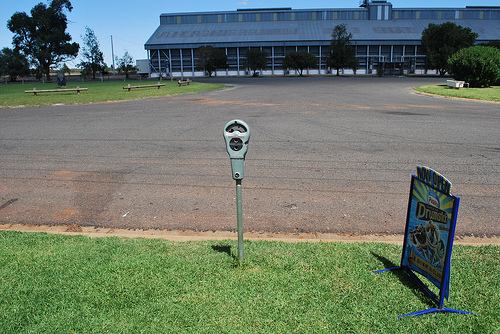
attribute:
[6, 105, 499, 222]
parking lot — large, empty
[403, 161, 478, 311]
signs — colorful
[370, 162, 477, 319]
sign — in the picture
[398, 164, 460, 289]
sign — colorful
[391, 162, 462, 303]
frame — blue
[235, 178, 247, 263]
pole — in the picture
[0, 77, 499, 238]
road — in the picture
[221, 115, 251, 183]
meter — alone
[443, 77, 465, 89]
bench — white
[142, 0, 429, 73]
building — screened in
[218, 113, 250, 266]
meter — metal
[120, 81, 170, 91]
wooden bench — small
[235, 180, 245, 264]
pole — in the picture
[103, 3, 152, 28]
sky — in the picture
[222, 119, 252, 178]
parking meter — in the picture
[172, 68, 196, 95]
bench — wooden, small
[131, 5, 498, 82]
building — in the picture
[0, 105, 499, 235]
roadway — paved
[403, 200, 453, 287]
background — blue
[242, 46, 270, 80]
tree — large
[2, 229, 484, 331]
grass — thick, green, in the picture